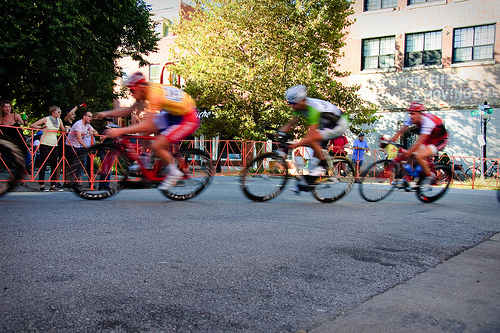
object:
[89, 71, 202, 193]
person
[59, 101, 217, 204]
bike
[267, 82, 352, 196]
person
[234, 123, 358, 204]
bike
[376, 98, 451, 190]
person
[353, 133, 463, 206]
bike